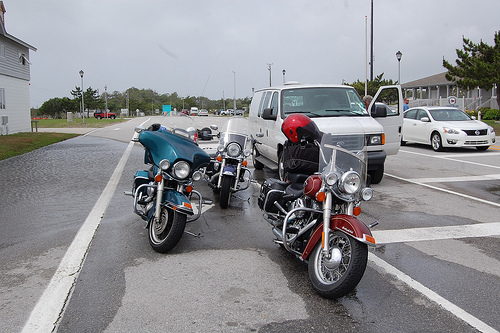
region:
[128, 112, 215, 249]
Turquoise motorcycle on a street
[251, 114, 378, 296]
Red motorcycle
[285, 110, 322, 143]
red motorcycle helmet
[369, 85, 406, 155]
open van door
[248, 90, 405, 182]
van with open door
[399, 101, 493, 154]
white car on a street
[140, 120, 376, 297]
Three motorcycles parked in street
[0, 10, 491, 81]
gray sky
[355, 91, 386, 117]
man standing by van door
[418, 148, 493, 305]
lines painted on the street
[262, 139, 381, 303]
Red motorcycle that is parked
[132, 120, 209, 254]
Blue motorcycle that is parked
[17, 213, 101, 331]
White line in the road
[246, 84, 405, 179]
White van with door open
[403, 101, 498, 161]
White car parked beside van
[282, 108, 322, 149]
Red helmet on top of motorcycle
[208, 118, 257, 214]
Motorcycle parked between other motorcycles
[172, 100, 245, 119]
Cars that are parked in parking lot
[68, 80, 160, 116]
Trees in the distance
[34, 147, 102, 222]
Water on the road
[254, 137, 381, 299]
red motorcycle sitting on edge of road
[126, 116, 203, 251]
blue motorcycle sitting on edge of road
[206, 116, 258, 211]
motorcycle sitting behind and in between red and blue motorcycle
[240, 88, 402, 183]
white van with door open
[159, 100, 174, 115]
large blue green sign in the background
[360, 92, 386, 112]
man standing on the inside of the doorway of the white van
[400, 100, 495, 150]
white carto the right of the white van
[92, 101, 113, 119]
red truck sitting on a side street in the back of the photograph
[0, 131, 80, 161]
grassy patch next to white building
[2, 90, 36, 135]
brick building painted white on the left side of the photo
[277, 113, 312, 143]
a red motorcycle helmet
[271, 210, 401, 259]
a red motorcycle fender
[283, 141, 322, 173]
a sleeping bag on back of motorcycle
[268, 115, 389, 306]
a red motorcycle sitting in street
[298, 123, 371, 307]
a windshield on motorcycle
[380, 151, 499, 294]
a street with white lines for parking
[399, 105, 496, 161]
a white car parked across street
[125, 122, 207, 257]
a blue motorcycle parked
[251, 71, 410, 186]
a white van parked with door open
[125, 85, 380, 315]
a group of motorcycles parked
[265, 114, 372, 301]
black and red motorcycle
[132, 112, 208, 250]
blue and black motorcycle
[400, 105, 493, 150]
white nissan sedan on street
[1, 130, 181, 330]
street is partially flooded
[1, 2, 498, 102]
white and grey sky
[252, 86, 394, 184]
white van with open door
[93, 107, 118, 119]
red and black jeep in distance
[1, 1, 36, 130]
grey and white house on side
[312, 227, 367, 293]
black tire with silver spokes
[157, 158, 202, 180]
round and silver headlights